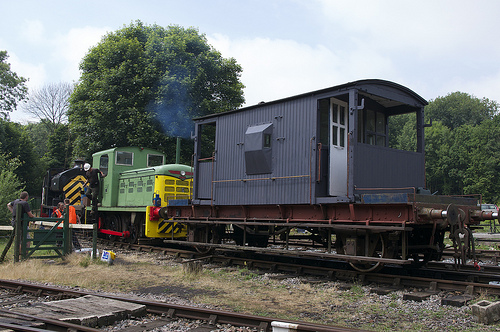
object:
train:
[42, 75, 493, 274]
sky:
[0, 1, 497, 97]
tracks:
[75, 234, 500, 299]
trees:
[64, 18, 247, 195]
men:
[6, 190, 36, 257]